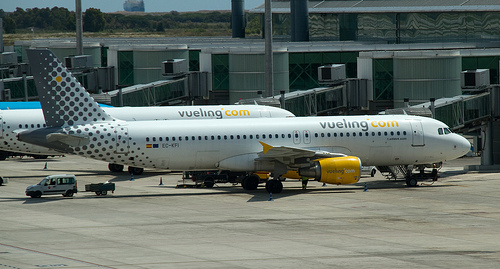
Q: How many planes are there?
A: Two.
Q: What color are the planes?
A: White, gray, yellow, and blue.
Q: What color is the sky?
A: Blue.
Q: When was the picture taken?
A: Daytime.